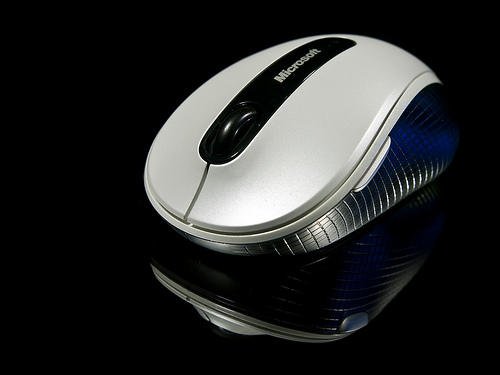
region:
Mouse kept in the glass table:
[136, 36, 454, 246]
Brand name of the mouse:
[268, 40, 341, 85]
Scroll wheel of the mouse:
[212, 104, 254, 154]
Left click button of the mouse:
[246, 164, 284, 213]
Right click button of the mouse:
[158, 143, 187, 190]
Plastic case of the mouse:
[300, 103, 350, 157]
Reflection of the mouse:
[154, 260, 448, 333]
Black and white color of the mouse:
[179, 82, 399, 221]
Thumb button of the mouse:
[356, 140, 403, 195]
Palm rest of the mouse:
[286, 26, 346, 78]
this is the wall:
[105, 32, 131, 44]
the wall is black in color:
[34, 230, 113, 300]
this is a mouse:
[135, 25, 469, 270]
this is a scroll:
[208, 105, 258, 155]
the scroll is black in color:
[223, 112, 242, 129]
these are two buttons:
[168, 118, 298, 203]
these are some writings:
[263, 47, 327, 83]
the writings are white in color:
[273, 42, 321, 90]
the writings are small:
[278, 48, 324, 72]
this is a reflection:
[290, 283, 342, 333]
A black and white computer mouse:
[126, 62, 463, 197]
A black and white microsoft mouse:
[254, 39, 331, 84]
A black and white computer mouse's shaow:
[152, 260, 417, 335]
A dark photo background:
[25, 227, 144, 322]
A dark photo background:
[421, 270, 493, 365]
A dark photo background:
[8, 144, 111, 216]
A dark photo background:
[10, 34, 106, 134]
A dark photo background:
[102, 2, 154, 81]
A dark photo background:
[261, 5, 369, 29]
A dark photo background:
[408, 1, 490, 74]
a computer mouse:
[143, 30, 463, 246]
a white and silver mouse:
[148, 25, 465, 249]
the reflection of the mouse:
[146, 236, 412, 342]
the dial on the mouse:
[212, 100, 252, 156]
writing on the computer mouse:
[273, 42, 325, 82]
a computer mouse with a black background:
[155, 32, 446, 242]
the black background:
[11, 40, 144, 362]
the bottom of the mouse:
[186, 188, 456, 239]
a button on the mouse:
[337, 305, 382, 337]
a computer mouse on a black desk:
[158, 30, 464, 252]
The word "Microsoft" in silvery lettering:
[262, 41, 332, 88]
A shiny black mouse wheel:
[191, 98, 278, 170]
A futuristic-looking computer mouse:
[135, 22, 460, 266]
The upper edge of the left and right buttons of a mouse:
[148, 151, 265, 235]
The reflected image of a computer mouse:
[137, 243, 408, 352]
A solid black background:
[12, 13, 118, 182]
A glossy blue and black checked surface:
[400, 128, 445, 173]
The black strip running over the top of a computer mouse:
[193, 23, 360, 169]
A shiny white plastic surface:
[257, 139, 322, 189]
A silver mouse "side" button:
[335, 307, 377, 339]